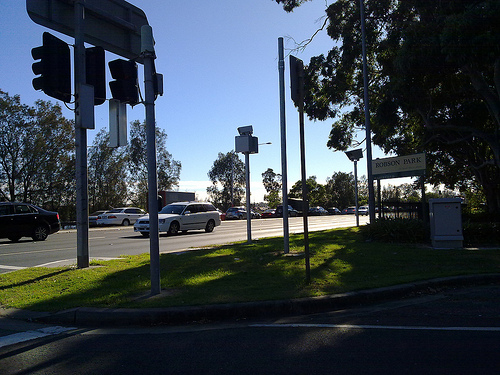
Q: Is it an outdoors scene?
A: Yes, it is outdoors.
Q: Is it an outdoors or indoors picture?
A: It is outdoors.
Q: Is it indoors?
A: No, it is outdoors.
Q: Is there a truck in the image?
A: No, there are no trucks.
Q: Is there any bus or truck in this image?
A: No, there are no trucks or buses.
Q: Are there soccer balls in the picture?
A: No, there are no soccer balls.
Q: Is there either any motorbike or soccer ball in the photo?
A: No, there are no soccer balls or motorcycles.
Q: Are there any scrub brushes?
A: No, there are no scrub brushes.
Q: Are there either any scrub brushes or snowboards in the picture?
A: No, there are no scrub brushes or snowboards.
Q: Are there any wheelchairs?
A: No, there are no wheelchairs.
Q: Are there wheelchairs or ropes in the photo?
A: No, there are no wheelchairs or ropes.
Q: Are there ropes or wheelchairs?
A: No, there are no wheelchairs or ropes.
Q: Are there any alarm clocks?
A: No, there are no alarm clocks.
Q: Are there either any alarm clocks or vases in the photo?
A: No, there are no alarm clocks or vases.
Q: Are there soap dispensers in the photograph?
A: No, there are no soap dispensers.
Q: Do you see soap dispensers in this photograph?
A: No, there are no soap dispensers.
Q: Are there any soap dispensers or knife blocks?
A: No, there are no soap dispensers or knife blocks.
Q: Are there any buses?
A: No, there are no buses.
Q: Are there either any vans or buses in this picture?
A: No, there are no buses or vans.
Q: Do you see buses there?
A: No, there are no buses.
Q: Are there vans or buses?
A: No, there are no buses or vans.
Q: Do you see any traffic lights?
A: Yes, there is a traffic light.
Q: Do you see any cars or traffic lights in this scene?
A: Yes, there is a traffic light.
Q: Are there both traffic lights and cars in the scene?
A: Yes, there are both a traffic light and a car.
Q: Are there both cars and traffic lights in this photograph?
A: Yes, there are both a traffic light and a car.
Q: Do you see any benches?
A: No, there are no benches.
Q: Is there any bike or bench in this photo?
A: No, there are no benches or bikes.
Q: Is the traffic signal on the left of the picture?
A: Yes, the traffic signal is on the left of the image.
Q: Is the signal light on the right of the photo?
A: No, the signal light is on the left of the image.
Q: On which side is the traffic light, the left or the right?
A: The traffic light is on the left of the image.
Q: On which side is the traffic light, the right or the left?
A: The traffic light is on the left of the image.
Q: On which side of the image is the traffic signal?
A: The traffic signal is on the left of the image.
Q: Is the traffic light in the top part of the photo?
A: Yes, the traffic light is in the top of the image.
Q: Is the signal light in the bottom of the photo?
A: No, the signal light is in the top of the image.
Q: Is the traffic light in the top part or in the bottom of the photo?
A: The traffic light is in the top of the image.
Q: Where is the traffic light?
A: The traffic light is at the intersection.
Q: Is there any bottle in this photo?
A: No, there are no bottles.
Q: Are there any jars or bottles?
A: No, there are no bottles or jars.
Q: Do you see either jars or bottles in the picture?
A: No, there are no bottles or jars.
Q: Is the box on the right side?
A: Yes, the box is on the right of the image.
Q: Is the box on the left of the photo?
A: No, the box is on the right of the image.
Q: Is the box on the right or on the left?
A: The box is on the right of the image.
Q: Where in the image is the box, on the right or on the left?
A: The box is on the right of the image.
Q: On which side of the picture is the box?
A: The box is on the right of the image.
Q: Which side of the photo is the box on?
A: The box is on the right of the image.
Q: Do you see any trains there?
A: No, there are no trains.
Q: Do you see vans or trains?
A: No, there are no trains or vans.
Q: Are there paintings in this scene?
A: No, there are no paintings.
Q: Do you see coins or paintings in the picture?
A: No, there are no paintings or coins.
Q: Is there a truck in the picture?
A: No, there are no trucks.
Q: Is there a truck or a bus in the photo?
A: No, there are no trucks or buses.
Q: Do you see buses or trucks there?
A: No, there are no trucks or buses.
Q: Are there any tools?
A: No, there are no tools.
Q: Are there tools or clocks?
A: No, there are no tools or clocks.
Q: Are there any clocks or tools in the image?
A: No, there are no tools or clocks.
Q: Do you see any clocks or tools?
A: No, there are no tools or clocks.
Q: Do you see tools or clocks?
A: No, there are no tools or clocks.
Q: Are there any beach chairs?
A: No, there are no beach chairs.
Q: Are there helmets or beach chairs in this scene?
A: No, there are no beach chairs or helmets.